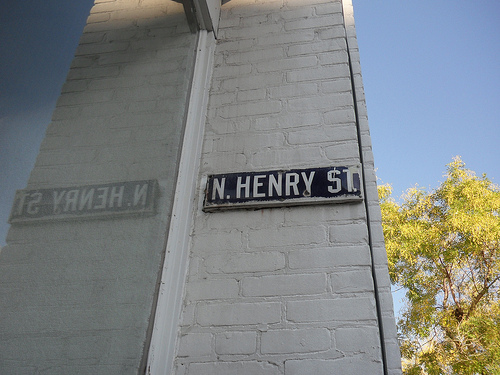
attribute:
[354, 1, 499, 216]
sky — cloudless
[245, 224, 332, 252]
brick — White 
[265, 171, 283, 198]
letters — white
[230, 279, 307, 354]
brick — painted, white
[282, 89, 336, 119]
brick — White 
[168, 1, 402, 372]
column — White 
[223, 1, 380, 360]
brick — white, painted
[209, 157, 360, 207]
sign — wooden, old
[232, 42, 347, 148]
wall — gray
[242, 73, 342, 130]
brick — White 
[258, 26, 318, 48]
brick — White 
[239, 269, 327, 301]
brick — painted, white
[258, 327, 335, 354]
white brick — painted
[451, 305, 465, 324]
nest — brown 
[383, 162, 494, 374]
tree top — large, green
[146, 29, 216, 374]
window frame — White 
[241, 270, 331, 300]
brick — white, painted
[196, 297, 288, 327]
brick — white, painted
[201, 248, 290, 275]
brick — white, painted